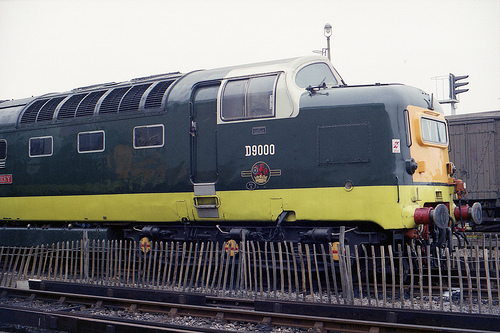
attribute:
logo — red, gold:
[230, 137, 290, 183]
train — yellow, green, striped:
[51, 60, 486, 297]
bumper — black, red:
[394, 180, 495, 231]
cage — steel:
[425, 68, 489, 107]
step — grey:
[176, 177, 236, 221]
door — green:
[170, 77, 236, 169]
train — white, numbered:
[104, 69, 464, 259]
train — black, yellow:
[29, 54, 464, 255]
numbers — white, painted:
[227, 130, 311, 177]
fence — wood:
[116, 237, 398, 318]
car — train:
[6, 54, 485, 252]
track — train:
[7, 280, 495, 330]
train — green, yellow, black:
[1, 54, 491, 285]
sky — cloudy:
[4, 1, 494, 117]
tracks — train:
[2, 236, 499, 331]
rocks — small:
[125, 312, 196, 327]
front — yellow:
[403, 101, 474, 197]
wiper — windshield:
[303, 75, 333, 111]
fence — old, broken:
[4, 233, 496, 326]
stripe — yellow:
[1, 180, 453, 235]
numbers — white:
[240, 139, 283, 161]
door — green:
[178, 80, 226, 208]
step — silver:
[192, 180, 216, 202]